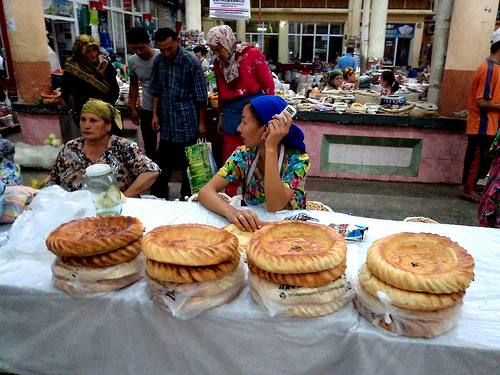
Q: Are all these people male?
A: No, they are both male and female.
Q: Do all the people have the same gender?
A: No, they are both male and female.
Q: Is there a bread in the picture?
A: Yes, there is a bread.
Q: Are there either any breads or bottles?
A: Yes, there is a bread.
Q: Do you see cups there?
A: No, there are no cups.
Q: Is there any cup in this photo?
A: No, there are no cups.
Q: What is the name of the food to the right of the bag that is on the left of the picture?
A: The food is a bread.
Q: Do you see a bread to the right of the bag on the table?
A: Yes, there is a bread to the right of the bag.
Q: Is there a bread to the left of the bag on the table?
A: No, the bread is to the right of the bag.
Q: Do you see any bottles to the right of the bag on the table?
A: No, there is a bread to the right of the bag.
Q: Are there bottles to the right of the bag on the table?
A: No, there is a bread to the right of the bag.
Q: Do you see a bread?
A: Yes, there is a bread.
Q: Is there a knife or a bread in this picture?
A: Yes, there is a bread.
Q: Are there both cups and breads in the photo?
A: No, there is a bread but no cups.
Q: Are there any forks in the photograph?
A: No, there are no forks.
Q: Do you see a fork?
A: No, there are no forks.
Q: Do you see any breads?
A: Yes, there is a bread.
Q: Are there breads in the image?
A: Yes, there is a bread.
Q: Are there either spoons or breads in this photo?
A: Yes, there is a bread.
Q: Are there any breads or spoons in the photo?
A: Yes, there is a bread.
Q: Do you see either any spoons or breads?
A: Yes, there is a bread.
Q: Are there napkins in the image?
A: No, there are no napkins.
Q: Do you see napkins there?
A: No, there are no napkins.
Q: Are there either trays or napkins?
A: No, there are no napkins or trays.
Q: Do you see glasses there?
A: No, there are no glasses.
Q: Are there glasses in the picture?
A: No, there are no glasses.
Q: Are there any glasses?
A: No, there are no glasses.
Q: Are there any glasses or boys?
A: No, there are no glasses or boys.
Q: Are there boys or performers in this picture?
A: No, there are no boys or performers.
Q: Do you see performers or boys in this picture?
A: No, there are no boys or performers.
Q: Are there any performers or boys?
A: No, there are no boys or performers.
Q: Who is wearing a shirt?
A: The man is wearing a shirt.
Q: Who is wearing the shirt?
A: The man is wearing a shirt.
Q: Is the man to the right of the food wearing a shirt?
A: Yes, the man is wearing a shirt.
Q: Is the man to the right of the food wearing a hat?
A: No, the man is wearing a shirt.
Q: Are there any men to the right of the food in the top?
A: Yes, there is a man to the right of the food.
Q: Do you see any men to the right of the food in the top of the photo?
A: Yes, there is a man to the right of the food.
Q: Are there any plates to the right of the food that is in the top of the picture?
A: No, there is a man to the right of the food.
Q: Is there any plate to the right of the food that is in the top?
A: No, there is a man to the right of the food.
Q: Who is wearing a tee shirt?
A: The man is wearing a tee shirt.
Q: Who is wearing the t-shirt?
A: The man is wearing a tee shirt.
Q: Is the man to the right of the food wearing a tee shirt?
A: Yes, the man is wearing a tee shirt.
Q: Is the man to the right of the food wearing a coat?
A: No, the man is wearing a tee shirt.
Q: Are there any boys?
A: No, there are no boys.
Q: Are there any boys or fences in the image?
A: No, there are no boys or fences.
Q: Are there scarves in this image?
A: Yes, there is a scarf.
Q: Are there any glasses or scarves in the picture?
A: Yes, there is a scarf.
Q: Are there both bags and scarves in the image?
A: Yes, there are both a scarf and a bag.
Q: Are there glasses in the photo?
A: No, there are no glasses.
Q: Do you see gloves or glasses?
A: No, there are no glasses or gloves.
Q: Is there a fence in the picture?
A: No, there are no fences.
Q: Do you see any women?
A: Yes, there is a woman.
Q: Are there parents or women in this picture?
A: Yes, there is a woman.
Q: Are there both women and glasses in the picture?
A: No, there is a woman but no glasses.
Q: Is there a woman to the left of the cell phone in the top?
A: Yes, there is a woman to the left of the cell phone.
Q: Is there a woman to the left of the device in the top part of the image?
A: Yes, there is a woman to the left of the cell phone.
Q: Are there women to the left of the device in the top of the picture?
A: Yes, there is a woman to the left of the cell phone.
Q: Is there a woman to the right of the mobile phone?
A: No, the woman is to the left of the mobile phone.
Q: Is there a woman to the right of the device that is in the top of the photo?
A: No, the woman is to the left of the mobile phone.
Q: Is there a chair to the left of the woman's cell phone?
A: No, there is a woman to the left of the cellphone.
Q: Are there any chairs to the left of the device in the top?
A: No, there is a woman to the left of the cellphone.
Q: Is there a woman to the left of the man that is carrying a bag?
A: Yes, there is a woman to the left of the man.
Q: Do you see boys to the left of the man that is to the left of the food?
A: No, there is a woman to the left of the man.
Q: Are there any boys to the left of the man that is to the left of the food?
A: No, there is a woman to the left of the man.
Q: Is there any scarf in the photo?
A: Yes, there is a scarf.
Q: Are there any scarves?
A: Yes, there is a scarf.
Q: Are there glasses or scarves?
A: Yes, there is a scarf.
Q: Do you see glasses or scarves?
A: Yes, there is a scarf.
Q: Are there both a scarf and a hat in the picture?
A: No, there is a scarf but no hats.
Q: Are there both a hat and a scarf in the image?
A: No, there is a scarf but no hats.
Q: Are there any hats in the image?
A: No, there are no hats.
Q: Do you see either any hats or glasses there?
A: No, there are no hats or glasses.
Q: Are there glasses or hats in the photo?
A: No, there are no hats or glasses.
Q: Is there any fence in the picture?
A: No, there are no fences.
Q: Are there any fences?
A: No, there are no fences.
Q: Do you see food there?
A: Yes, there is food.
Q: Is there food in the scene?
A: Yes, there is food.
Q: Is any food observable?
A: Yes, there is food.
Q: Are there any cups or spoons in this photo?
A: No, there are no cups or spoons.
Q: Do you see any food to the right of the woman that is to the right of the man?
A: Yes, there is food to the right of the woman.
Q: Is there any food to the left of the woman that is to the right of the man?
A: No, the food is to the right of the woman.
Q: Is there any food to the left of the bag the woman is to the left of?
A: No, the food is to the right of the bag.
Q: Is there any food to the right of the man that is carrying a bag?
A: Yes, there is food to the right of the man.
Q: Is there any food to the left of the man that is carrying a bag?
A: No, the food is to the right of the man.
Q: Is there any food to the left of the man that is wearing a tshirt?
A: Yes, there is food to the left of the man.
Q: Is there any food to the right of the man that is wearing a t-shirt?
A: No, the food is to the left of the man.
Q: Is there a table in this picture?
A: Yes, there is a table.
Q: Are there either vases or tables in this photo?
A: Yes, there is a table.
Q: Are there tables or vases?
A: Yes, there is a table.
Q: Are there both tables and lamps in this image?
A: No, there is a table but no lamps.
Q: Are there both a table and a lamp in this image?
A: No, there is a table but no lamps.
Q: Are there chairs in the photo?
A: No, there are no chairs.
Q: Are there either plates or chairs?
A: No, there are no chairs or plates.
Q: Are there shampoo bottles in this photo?
A: No, there are no shampoo bottles.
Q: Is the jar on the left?
A: Yes, the jar is on the left of the image.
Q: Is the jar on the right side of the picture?
A: No, the jar is on the left of the image.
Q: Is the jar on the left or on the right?
A: The jar is on the left of the image.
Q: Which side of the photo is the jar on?
A: The jar is on the left of the image.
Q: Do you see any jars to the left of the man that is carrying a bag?
A: Yes, there is a jar to the left of the man.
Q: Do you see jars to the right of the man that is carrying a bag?
A: No, the jar is to the left of the man.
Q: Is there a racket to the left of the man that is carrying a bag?
A: No, there is a jar to the left of the man.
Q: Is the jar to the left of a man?
A: Yes, the jar is to the left of a man.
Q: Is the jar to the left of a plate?
A: No, the jar is to the left of a man.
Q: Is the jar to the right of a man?
A: No, the jar is to the left of a man.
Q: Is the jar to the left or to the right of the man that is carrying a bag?
A: The jar is to the left of the man.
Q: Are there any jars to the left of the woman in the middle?
A: Yes, there is a jar to the left of the woman.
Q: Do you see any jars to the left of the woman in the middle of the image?
A: Yes, there is a jar to the left of the woman.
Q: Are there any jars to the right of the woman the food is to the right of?
A: No, the jar is to the left of the woman.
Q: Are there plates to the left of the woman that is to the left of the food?
A: No, there is a jar to the left of the woman.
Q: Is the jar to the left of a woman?
A: Yes, the jar is to the left of a woman.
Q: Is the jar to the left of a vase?
A: No, the jar is to the left of a woman.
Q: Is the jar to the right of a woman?
A: No, the jar is to the left of a woman.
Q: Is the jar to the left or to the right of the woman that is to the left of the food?
A: The jar is to the left of the woman.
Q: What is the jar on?
A: The jar is on the table.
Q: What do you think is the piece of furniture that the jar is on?
A: The piece of furniture is a table.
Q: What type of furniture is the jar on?
A: The jar is on the table.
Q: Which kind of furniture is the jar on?
A: The jar is on the table.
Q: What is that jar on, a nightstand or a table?
A: The jar is on a table.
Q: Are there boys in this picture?
A: No, there are no boys.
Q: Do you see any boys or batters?
A: No, there are no boys or batters.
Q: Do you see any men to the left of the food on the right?
A: Yes, there is a man to the left of the food.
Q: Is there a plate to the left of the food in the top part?
A: No, there is a man to the left of the food.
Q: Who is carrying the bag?
A: The man is carrying the bag.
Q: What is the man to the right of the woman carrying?
A: The man is carrying a bag.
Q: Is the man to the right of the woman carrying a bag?
A: Yes, the man is carrying a bag.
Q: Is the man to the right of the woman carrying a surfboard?
A: No, the man is carrying a bag.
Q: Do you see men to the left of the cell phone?
A: Yes, there is a man to the left of the cell phone.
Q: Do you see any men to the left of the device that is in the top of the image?
A: Yes, there is a man to the left of the cell phone.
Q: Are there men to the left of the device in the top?
A: Yes, there is a man to the left of the cell phone.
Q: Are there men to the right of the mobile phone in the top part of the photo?
A: No, the man is to the left of the cell phone.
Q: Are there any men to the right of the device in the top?
A: No, the man is to the left of the cell phone.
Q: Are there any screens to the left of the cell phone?
A: No, there is a man to the left of the cell phone.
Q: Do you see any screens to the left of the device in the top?
A: No, there is a man to the left of the cell phone.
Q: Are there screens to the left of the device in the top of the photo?
A: No, there is a man to the left of the cell phone.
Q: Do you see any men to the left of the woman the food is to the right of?
A: Yes, there is a man to the left of the woman.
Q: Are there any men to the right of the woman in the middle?
A: No, the man is to the left of the woman.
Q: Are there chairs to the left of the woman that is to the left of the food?
A: No, there is a man to the left of the woman.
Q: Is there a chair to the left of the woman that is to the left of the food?
A: No, there is a man to the left of the woman.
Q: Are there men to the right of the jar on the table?
A: Yes, there is a man to the right of the jar.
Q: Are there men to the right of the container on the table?
A: Yes, there is a man to the right of the jar.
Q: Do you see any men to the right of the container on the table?
A: Yes, there is a man to the right of the jar.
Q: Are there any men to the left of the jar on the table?
A: No, the man is to the right of the jar.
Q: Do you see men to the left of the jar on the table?
A: No, the man is to the right of the jar.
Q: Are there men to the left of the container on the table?
A: No, the man is to the right of the jar.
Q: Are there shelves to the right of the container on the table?
A: No, there is a man to the right of the jar.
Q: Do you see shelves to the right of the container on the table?
A: No, there is a man to the right of the jar.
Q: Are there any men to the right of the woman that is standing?
A: Yes, there is a man to the right of the woman.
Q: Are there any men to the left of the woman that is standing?
A: No, the man is to the right of the woman.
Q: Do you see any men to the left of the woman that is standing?
A: No, the man is to the right of the woman.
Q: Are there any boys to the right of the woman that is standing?
A: No, there is a man to the right of the woman.